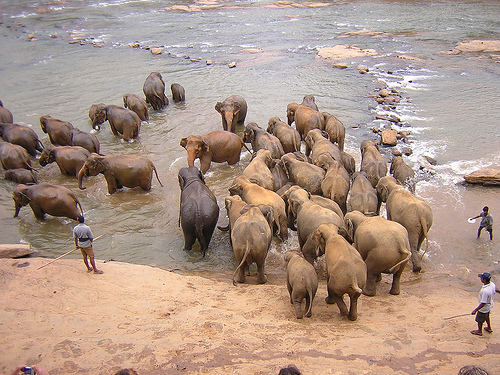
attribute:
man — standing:
[67, 215, 99, 274]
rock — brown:
[466, 161, 493, 191]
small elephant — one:
[169, 80, 204, 125]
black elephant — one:
[177, 210, 240, 286]